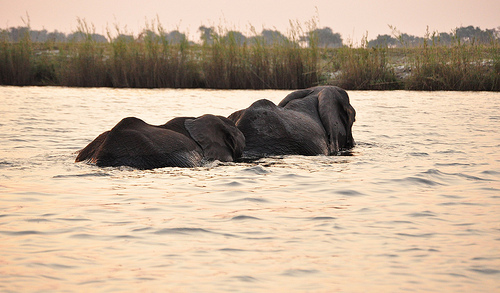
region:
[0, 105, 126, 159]
elephant walking in water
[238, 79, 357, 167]
elephant walking in water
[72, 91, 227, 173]
elephant walking in water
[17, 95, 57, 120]
calm gray water in river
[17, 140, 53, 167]
calm gray water in river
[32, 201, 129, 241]
calm gray water in river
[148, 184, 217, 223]
calm gray water in river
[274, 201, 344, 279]
calm gray water in river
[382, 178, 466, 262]
calm gray water in river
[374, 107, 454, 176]
calm gray water in river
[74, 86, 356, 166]
two elephants in the water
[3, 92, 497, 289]
large body of water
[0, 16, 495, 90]
plants next to a body of water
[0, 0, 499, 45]
sky is light pink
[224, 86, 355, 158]
top half of an elephant in the water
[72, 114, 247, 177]
elephant submerged in the water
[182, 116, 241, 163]
right ear of an elephant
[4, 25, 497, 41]
silhouette of trees on the horizon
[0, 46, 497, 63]
large open field next to the water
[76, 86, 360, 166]
two elephants bathing in the water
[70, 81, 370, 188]
Two elephants half way submerged in water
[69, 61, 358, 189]
The leading elephant is bigger than the other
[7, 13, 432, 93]
Tall grass on the bank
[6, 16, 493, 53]
Lots of trees in the distance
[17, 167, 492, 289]
Small waves on the water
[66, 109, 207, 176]
Contour of the elephants spine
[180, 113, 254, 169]
Big floppy elephant ear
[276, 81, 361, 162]
Ears pulled back tight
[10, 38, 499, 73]
Shorter grass lies beyond the tall grass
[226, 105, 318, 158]
Lots of wrinkly skin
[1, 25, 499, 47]
treeline in the distance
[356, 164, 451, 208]
small wave in the water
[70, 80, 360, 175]
two elephants wading through a body of water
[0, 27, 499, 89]
grassy area along on riverbank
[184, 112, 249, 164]
elephant's ear at water level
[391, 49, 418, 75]
dry land without plants growing on it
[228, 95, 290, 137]
bony hump on back rear of elephant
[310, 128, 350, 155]
wet grey elephant skin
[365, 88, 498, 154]
open water space between elephants and land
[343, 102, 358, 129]
elephant's eye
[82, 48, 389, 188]
Elephants swimming in the water.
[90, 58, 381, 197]
Two elephants in the water.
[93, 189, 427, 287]
The water is calm.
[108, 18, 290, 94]
The grass is tall.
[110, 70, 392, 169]
The elephants are gray.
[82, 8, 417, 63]
Trees in the background.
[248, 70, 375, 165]
A mother elephant in the water.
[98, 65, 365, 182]
Baby elephant is behind mother elephant.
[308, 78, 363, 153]
The elephant head is above the water.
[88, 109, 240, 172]
The elephant is wet.